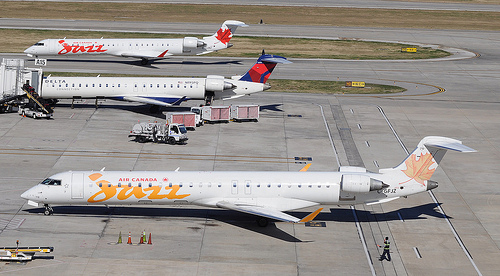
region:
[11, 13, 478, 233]
three planes on runway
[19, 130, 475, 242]
large white airplane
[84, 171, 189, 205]
logo on side of plane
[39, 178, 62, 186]
windshield on white plane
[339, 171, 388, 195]
engine on white plane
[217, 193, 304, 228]
wing of white plane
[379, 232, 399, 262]
man standing on runway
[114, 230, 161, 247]
group of people standing next to plane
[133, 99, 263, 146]
luggage trucks next to plane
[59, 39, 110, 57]
red logo on white plane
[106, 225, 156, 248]
cones on the tarmac next to the plane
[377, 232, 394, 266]
a man walking towards the plane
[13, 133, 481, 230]
an air canada plane on the tarmac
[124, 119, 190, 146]
a white truck on the tarmac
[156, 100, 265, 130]
luggage carriers next to the plane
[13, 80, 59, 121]
a stairway truck next to the plane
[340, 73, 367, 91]
a yellow runway marker sign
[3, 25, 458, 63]
a grass runway divider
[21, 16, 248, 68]
a plane taxiing on the runway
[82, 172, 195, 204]
yellow words on the side of the plane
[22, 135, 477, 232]
white color aeroplane in the airport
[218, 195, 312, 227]
wings of the aeroplane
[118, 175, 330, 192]
window of the aeroplane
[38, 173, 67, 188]
glass in front of the aeroplane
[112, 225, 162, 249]
some peoples atanding in the airport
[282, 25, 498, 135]
runway of the airport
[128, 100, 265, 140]
container in the airport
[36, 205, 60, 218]
wheel of the aeroplane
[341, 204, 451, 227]
shadow of the aeroplane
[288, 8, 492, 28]
dirt in the aeroplane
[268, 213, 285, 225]
edge of a wing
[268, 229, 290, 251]
part of a shade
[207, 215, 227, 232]
part of an airport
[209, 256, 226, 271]
part of a runway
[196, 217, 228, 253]
part of a floor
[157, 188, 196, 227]
part of a planr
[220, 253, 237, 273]
part of a floor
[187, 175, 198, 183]
part of a plane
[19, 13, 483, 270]
three planes parked on the ground at the airport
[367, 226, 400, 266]
man working at the airport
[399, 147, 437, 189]
orange maple leaf painted on plane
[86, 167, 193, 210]
Air Canada Jazz logo painted in orange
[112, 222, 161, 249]
neon orange and yellow safety cones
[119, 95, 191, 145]
airport cargo truck between two planes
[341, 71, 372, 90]
directional sign painted yellow and black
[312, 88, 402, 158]
lanes painted in white lines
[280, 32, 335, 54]
dead areas of grass between cement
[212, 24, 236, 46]
red maple leaf painted on plane